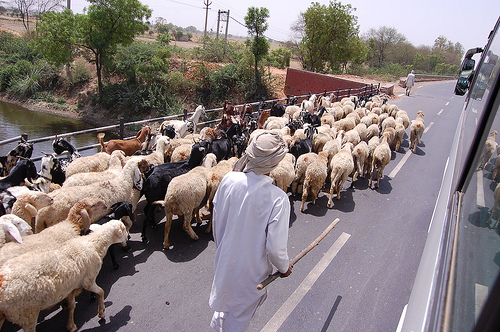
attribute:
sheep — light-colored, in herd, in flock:
[42, 82, 393, 278]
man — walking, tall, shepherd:
[215, 150, 291, 329]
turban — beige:
[233, 137, 281, 185]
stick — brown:
[270, 207, 337, 288]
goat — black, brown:
[128, 144, 218, 226]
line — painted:
[373, 125, 452, 164]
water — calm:
[3, 112, 95, 168]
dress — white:
[211, 178, 274, 322]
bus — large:
[448, 61, 496, 331]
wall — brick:
[284, 51, 343, 110]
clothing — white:
[209, 171, 290, 331]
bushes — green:
[22, 25, 293, 114]